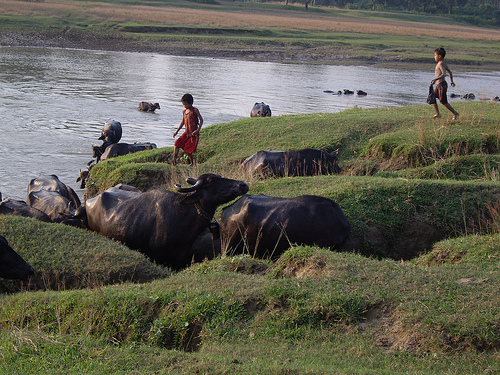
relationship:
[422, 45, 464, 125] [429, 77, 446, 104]
boy wearing shorts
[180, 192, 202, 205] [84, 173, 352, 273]
ear of cow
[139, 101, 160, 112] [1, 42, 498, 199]
cow in water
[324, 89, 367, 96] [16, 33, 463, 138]
cows in water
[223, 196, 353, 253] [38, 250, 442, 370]
hippo on ground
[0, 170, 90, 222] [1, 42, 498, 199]
hippo next to water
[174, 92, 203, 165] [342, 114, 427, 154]
boy standing on grass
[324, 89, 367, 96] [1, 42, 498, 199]
cows walking in water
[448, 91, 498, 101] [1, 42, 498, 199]
cows walking in water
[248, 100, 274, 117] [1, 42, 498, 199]
cow walking in water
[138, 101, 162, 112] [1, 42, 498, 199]
cow walking in water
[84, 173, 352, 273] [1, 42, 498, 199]
cow walking in water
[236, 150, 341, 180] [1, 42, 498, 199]
cow walking in water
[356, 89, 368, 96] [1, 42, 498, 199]
cow walking in water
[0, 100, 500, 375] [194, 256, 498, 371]
grass on top of ground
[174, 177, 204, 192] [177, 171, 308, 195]
horn on top of head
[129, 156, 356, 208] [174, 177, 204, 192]
cow has horn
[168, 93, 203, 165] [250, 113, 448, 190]
boy standing on grass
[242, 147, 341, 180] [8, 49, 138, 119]
cow walking in water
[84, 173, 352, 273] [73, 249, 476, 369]
cow standing in hillside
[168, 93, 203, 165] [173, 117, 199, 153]
boy wearing clothing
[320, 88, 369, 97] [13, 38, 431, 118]
cows inside of lake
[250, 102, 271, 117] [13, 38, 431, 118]
cow inside of lake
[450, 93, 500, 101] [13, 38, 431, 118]
cows inside of lake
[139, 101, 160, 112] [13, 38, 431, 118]
cow inside of lake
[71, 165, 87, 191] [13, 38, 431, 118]
cows inside of lake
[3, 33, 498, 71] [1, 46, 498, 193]
bank next to lake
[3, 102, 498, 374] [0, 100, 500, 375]
grass on top of grass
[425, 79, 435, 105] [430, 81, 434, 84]
shirt in hand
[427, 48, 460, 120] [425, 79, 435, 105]
boy holding shirt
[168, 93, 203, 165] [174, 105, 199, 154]
boy wearing clothing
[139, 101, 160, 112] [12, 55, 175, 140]
cow walking in water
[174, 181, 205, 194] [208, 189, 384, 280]
horn on buffalo